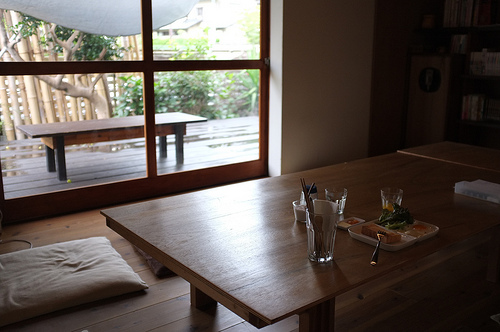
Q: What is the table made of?
A: Wood.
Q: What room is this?
A: Dining room.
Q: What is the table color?
A: Brown.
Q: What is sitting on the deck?
A: Bench.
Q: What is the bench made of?
A: Wood.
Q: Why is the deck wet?
A: Rained.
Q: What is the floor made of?
A: Wood.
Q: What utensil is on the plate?
A: Fork.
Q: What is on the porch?
A: Bench.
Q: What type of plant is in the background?
A: Tree.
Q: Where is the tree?
A: Outside the window.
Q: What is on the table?
A: Food.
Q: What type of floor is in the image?
A: Wooden.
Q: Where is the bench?
A: On the deck.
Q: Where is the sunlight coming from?
A: The window.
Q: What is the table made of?
A: Wood.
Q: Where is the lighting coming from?
A: Outside the window.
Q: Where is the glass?
A: On the table.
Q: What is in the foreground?
A: A wooden table.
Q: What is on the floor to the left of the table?
A: A pillow.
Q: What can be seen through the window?
A: A bench.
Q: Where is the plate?
A: On the table.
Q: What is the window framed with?
A: Wood.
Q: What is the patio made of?
A: Wood.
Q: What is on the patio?
A: A bench.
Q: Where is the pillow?
A: On the floor.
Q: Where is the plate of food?
A: On the table.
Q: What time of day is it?
A: Daytime.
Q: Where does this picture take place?
A: In a house.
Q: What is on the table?
A: Dishes and a meal.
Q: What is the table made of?
A: Wood.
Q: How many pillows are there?
A: Two.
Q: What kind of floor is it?
A: Hardwood.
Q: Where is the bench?
A: On the deck.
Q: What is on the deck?
A: Water.